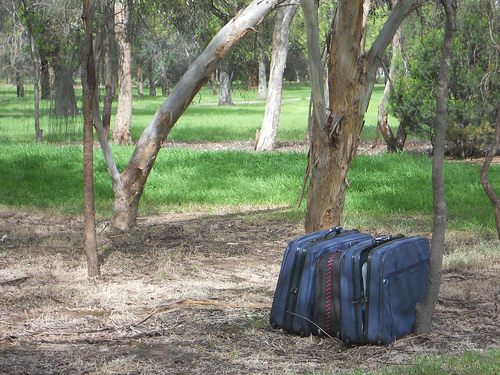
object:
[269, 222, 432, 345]
suitcase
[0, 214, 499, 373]
ground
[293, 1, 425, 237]
tree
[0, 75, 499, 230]
grass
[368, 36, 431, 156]
vines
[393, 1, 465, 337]
tree